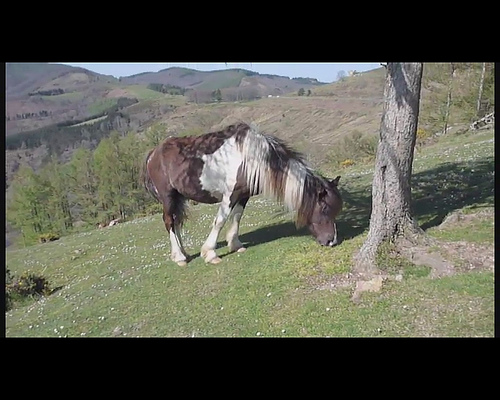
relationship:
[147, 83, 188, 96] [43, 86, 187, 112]
trees on hillside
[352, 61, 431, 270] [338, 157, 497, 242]
tree has shadow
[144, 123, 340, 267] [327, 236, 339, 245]
pony has nose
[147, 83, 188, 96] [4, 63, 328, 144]
trees on hills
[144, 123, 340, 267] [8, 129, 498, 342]
pony on hill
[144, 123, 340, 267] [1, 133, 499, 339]
pony eating grass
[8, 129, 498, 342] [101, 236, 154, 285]
hill has flowers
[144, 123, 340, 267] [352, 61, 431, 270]
pony next to tree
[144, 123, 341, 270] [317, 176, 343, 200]
pony has ears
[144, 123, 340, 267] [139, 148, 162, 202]
pony has tail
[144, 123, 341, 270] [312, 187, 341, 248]
pony has face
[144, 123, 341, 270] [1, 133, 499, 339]
pony eats grass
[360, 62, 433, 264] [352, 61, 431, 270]
trunk of tree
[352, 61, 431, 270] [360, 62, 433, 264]
tree has trunk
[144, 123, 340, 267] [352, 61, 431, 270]
pony by tree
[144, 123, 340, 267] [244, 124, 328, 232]
pony has mane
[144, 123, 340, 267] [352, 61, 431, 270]
pony near tree